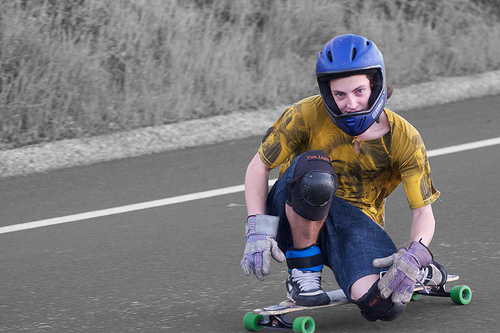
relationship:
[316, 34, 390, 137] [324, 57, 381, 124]
helmet on top of head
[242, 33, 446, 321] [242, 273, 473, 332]
boy riding skateboard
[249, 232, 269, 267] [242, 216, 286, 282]
hand inside glove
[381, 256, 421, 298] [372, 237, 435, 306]
hand inside glove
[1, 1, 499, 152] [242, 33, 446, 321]
weeds behind boy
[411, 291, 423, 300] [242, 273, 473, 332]
wheel under skateboard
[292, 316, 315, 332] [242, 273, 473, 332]
wheel under skateboard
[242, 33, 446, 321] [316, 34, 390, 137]
boy wearing helmet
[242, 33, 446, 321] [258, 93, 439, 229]
boy wearing shirt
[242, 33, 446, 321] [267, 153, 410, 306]
boy wearing shorts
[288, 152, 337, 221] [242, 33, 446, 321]
knee pad on top of boy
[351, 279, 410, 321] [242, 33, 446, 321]
knee pad on top of boy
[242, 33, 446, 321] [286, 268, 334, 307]
boy wearing shoe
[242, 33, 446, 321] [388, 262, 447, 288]
boy wearing shoe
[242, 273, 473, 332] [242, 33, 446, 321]
skateboard under boy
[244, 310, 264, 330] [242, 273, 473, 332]
wheel under skateboard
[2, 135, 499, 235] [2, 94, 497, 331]
line on top of road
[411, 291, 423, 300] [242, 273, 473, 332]
wheel beneath skateboard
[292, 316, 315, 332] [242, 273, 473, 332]
wheel beneath skateboard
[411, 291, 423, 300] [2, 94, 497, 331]
wheel riding on pavement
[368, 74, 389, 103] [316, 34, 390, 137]
hair next to helmet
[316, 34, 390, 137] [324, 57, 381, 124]
helmet covering head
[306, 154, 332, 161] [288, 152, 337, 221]
print on top of knee pad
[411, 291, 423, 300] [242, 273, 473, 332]
wheel underneath skateboard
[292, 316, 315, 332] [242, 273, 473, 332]
wheel underneath skateboard